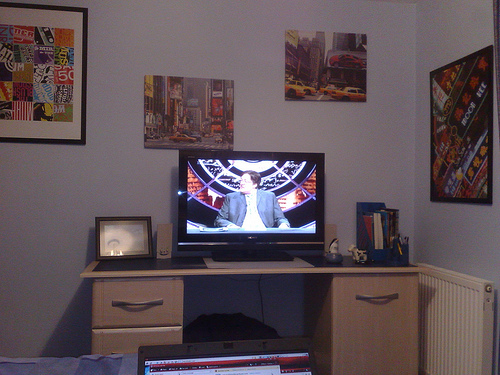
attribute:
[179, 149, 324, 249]
television — turned on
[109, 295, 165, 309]
handle — metal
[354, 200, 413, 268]
rack — small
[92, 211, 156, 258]
certificate — framed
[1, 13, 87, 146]
picture — framed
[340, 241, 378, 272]
figurine — small, animal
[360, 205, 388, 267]
holder — blue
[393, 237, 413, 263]
holder — blue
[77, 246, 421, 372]
desk — wooden, small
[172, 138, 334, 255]
television — turned on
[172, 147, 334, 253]
tv — on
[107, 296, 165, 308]
handle — small, metal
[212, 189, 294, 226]
jacket — gray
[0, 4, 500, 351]
wall — white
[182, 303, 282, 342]
object — dark